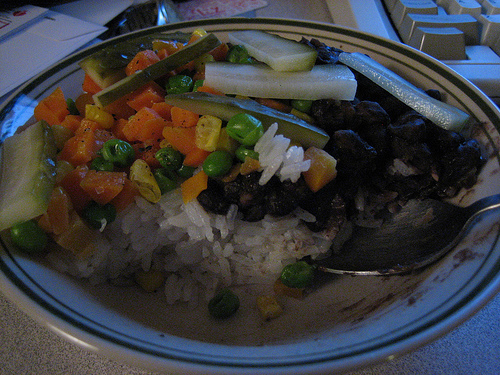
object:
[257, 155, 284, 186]
rice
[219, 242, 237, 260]
rice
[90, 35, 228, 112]
pickle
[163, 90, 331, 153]
pickle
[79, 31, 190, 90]
pickle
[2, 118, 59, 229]
pickle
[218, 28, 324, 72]
pickle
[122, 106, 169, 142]
carrot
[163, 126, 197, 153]
carrot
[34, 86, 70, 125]
carrot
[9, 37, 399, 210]
vegetables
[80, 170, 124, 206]
carrots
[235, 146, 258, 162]
peas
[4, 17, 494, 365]
dish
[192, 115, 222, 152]
corn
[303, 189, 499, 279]
spoon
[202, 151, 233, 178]
beans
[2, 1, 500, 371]
counter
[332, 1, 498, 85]
keyboard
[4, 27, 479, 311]
food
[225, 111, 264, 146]
beans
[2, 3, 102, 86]
letter